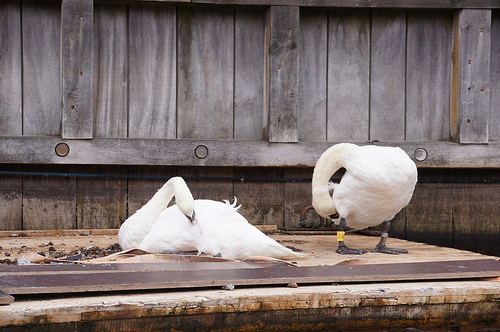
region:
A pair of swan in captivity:
[95, 129, 421, 278]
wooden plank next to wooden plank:
[2, 2, 24, 136]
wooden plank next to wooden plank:
[21, 4, 65, 136]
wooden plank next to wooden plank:
[63, 3, 97, 137]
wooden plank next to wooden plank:
[96, 1, 128, 133]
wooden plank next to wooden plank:
[128, 8, 178, 138]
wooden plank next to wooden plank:
[175, 0, 234, 139]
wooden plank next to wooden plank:
[235, 2, 269, 140]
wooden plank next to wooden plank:
[261, 4, 302, 142]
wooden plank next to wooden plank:
[296, 10, 326, 142]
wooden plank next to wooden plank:
[328, 9, 369, 142]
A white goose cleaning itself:
[311, 137, 419, 258]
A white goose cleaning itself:
[116, 172, 301, 267]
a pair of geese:
[115, 130, 418, 258]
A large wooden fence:
[0, 0, 499, 255]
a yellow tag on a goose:
[331, 227, 341, 238]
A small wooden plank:
[0, 255, 292, 270]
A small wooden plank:
[1, 250, 493, 296]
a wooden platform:
[0, 230, 495, 330]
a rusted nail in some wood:
[289, 91, 296, 98]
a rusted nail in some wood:
[275, 63, 283, 70]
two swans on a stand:
[96, 115, 431, 275]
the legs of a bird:
[335, 214, 412, 254]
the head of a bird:
[171, 175, 207, 232]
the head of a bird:
[306, 186, 344, 226]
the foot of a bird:
[374, 242, 407, 255]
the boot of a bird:
[331, 240, 373, 258]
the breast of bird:
[367, 153, 412, 210]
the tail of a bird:
[261, 235, 308, 271]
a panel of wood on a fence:
[21, 0, 75, 228]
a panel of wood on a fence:
[131, 4, 178, 232]